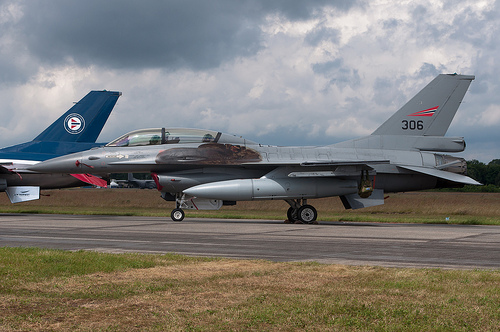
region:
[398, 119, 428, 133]
the number 306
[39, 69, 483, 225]
a gray powerful fighter ready to fly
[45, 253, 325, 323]
some dry grass in the field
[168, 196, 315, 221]
the landing system of the fighter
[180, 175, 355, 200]
a powerful missile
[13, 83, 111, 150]
part of a blue airplane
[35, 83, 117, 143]
the blue tail of the airplane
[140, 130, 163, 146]
the pilot inspecting the fighter control panel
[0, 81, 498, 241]
a couple of fighters ready to attack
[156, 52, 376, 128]
a cloudy sky int background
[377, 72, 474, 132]
grey tail of a plane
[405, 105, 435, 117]
red design on a plane's tail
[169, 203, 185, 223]
front landing gear on a plane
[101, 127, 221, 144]
cockpit of a fighter jet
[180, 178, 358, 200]
a fuel tank on a fighter jet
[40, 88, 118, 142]
blue tail of a plane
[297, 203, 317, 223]
rear wheel of a plane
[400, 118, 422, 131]
306 written in black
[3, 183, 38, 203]
tail wing on a plane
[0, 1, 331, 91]
dark cloud in the sky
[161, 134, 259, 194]
rust is on the jet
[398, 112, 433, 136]
306 numbers are on the tail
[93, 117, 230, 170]
two people are in the cockpit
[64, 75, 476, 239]
the plane is grey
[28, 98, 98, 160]
the tail is blue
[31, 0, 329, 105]
clouds are in the sky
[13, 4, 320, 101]
the clouds have rain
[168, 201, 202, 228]
the front tire is small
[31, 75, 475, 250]
the planes are parked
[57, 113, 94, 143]
a circle is on th tail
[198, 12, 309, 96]
sky above the land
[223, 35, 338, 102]
clouds in the sky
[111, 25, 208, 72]
dark cloud in the sky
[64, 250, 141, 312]
green and brown grass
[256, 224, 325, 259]
cement under the plane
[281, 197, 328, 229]
wheels on the plane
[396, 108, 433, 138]
the number 306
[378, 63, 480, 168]
tail of the plane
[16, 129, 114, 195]
nose of the plane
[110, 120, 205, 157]
cockpit of the plane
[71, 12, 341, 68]
this is the sky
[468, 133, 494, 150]
the sky is blue in color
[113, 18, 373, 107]
the sky has clouds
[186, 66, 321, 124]
the clouds are white in color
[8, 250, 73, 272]
this is the grass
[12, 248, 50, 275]
the grass is green in color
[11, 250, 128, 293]
the grass is short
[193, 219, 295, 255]
this is the runway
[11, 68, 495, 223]
these are two jets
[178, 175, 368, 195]
this is a missile